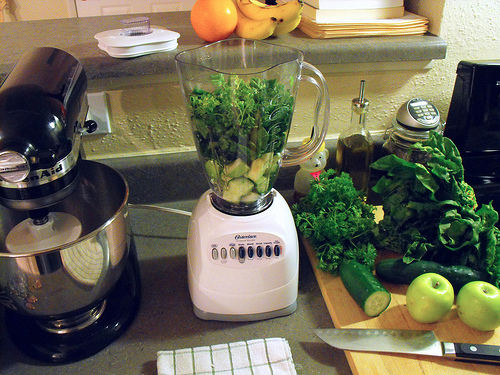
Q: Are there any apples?
A: Yes, there are apples.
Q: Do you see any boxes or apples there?
A: Yes, there are apples.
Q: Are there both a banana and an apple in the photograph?
A: Yes, there are both an apple and a banana.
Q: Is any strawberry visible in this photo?
A: No, there are no strawberries.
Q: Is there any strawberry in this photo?
A: No, there are no strawberries.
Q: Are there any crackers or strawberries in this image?
A: No, there are no strawberries or crackers.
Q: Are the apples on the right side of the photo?
A: Yes, the apples are on the right of the image.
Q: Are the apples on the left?
A: No, the apples are on the right of the image.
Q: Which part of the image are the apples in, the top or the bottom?
A: The apples are in the bottom of the image.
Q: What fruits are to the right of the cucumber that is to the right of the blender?
A: The fruits are apples.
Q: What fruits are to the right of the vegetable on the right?
A: The fruits are apples.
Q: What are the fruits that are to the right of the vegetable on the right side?
A: The fruits are apples.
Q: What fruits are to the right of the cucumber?
A: The fruits are apples.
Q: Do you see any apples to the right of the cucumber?
A: Yes, there are apples to the right of the cucumber.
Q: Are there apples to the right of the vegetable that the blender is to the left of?
A: Yes, there are apples to the right of the cucumber.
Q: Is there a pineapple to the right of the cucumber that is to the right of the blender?
A: No, there are apples to the right of the cucumber.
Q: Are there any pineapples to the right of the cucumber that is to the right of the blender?
A: No, there are apples to the right of the cucumber.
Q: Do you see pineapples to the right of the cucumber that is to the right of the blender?
A: No, there are apples to the right of the cucumber.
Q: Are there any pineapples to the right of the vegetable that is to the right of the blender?
A: No, there are apples to the right of the cucumber.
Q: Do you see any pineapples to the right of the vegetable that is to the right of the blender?
A: No, there are apples to the right of the cucumber.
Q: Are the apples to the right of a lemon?
A: No, the apples are to the right of the cucumber.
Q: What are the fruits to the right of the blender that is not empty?
A: The fruits are apples.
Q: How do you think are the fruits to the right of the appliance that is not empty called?
A: The fruits are apples.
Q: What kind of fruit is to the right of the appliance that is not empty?
A: The fruits are apples.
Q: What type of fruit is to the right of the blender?
A: The fruits are apples.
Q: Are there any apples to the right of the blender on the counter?
A: Yes, there are apples to the right of the blender.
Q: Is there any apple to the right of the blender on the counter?
A: Yes, there are apples to the right of the blender.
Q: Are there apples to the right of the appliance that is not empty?
A: Yes, there are apples to the right of the blender.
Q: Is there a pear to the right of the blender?
A: No, there are apples to the right of the blender.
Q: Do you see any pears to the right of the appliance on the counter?
A: No, there are apples to the right of the blender.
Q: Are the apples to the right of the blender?
A: Yes, the apples are to the right of the blender.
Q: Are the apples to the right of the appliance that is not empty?
A: Yes, the apples are to the right of the blender.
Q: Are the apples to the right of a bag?
A: No, the apples are to the right of the blender.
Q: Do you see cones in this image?
A: No, there are no cones.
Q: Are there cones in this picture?
A: No, there are no cones.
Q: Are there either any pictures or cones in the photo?
A: No, there are no cones or pictures.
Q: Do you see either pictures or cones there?
A: No, there are no cones or pictures.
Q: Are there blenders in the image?
A: Yes, there is a blender.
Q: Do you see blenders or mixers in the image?
A: Yes, there is a blender.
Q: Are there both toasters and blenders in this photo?
A: No, there is a blender but no toasters.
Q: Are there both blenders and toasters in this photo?
A: No, there is a blender but no toasters.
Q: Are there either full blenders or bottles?
A: Yes, there is a full blender.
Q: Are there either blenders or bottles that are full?
A: Yes, the blender is full.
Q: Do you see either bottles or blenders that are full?
A: Yes, the blender is full.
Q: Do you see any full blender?
A: Yes, there is a full blender.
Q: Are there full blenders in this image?
A: Yes, there is a full blender.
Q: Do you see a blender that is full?
A: Yes, there is a blender that is full.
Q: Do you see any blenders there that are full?
A: Yes, there is a blender that is full.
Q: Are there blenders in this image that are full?
A: Yes, there is a blender that is full.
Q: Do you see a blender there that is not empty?
A: Yes, there is an full blender.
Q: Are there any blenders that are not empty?
A: Yes, there is an full blender.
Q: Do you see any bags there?
A: No, there are no bags.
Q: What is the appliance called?
A: The appliance is a blender.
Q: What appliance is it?
A: The appliance is a blender.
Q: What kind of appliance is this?
A: That is a blender.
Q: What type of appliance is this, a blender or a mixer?
A: That is a blender.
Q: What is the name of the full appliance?
A: The appliance is a blender.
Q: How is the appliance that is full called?
A: The appliance is a blender.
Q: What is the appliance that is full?
A: The appliance is a blender.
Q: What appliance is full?
A: The appliance is a blender.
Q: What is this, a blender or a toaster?
A: This is a blender.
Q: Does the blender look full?
A: Yes, the blender is full.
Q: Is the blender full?
A: Yes, the blender is full.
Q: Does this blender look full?
A: Yes, the blender is full.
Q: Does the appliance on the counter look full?
A: Yes, the blender is full.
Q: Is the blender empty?
A: No, the blender is full.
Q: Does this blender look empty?
A: No, the blender is full.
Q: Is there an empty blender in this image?
A: No, there is a blender but it is full.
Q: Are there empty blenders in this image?
A: No, there is a blender but it is full.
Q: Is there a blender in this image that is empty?
A: No, there is a blender but it is full.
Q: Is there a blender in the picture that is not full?
A: No, there is a blender but it is full.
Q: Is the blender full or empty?
A: The blender is full.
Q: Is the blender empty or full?
A: The blender is full.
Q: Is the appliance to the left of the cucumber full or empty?
A: The blender is full.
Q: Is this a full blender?
A: Yes, this is a full blender.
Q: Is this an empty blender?
A: No, this is a full blender.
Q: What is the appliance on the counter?
A: The appliance is a blender.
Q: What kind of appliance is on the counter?
A: The appliance is a blender.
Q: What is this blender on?
A: The blender is on the counter.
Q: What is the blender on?
A: The blender is on the counter.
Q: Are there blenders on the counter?
A: Yes, there is a blender on the counter.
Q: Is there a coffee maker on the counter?
A: No, there is a blender on the counter.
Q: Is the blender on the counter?
A: Yes, the blender is on the counter.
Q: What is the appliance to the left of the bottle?
A: The appliance is a blender.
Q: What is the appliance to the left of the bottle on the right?
A: The appliance is a blender.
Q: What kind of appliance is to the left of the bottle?
A: The appliance is a blender.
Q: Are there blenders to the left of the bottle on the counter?
A: Yes, there is a blender to the left of the bottle.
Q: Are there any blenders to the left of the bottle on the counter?
A: Yes, there is a blender to the left of the bottle.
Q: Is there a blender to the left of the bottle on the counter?
A: Yes, there is a blender to the left of the bottle.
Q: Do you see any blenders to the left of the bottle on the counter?
A: Yes, there is a blender to the left of the bottle.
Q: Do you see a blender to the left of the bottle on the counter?
A: Yes, there is a blender to the left of the bottle.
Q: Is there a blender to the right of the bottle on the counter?
A: No, the blender is to the left of the bottle.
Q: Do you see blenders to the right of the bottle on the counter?
A: No, the blender is to the left of the bottle.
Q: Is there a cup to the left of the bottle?
A: No, there is a blender to the left of the bottle.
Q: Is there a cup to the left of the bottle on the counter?
A: No, there is a blender to the left of the bottle.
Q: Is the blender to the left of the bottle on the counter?
A: Yes, the blender is to the left of the bottle.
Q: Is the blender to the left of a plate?
A: No, the blender is to the left of the bottle.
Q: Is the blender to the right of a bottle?
A: No, the blender is to the left of a bottle.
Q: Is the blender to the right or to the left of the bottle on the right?
A: The blender is to the left of the bottle.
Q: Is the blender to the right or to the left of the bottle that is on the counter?
A: The blender is to the left of the bottle.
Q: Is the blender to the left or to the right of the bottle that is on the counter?
A: The blender is to the left of the bottle.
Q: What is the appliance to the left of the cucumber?
A: The appliance is a blender.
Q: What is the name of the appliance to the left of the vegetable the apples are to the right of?
A: The appliance is a blender.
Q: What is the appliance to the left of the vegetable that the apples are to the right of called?
A: The appliance is a blender.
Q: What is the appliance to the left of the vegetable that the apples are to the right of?
A: The appliance is a blender.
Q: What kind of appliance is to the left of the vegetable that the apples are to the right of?
A: The appliance is a blender.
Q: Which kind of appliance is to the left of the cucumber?
A: The appliance is a blender.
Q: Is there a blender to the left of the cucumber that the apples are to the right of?
A: Yes, there is a blender to the left of the cucumber.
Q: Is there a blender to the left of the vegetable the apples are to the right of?
A: Yes, there is a blender to the left of the cucumber.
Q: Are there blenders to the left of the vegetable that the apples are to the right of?
A: Yes, there is a blender to the left of the cucumber.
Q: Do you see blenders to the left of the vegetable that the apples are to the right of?
A: Yes, there is a blender to the left of the cucumber.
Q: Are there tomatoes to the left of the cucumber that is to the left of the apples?
A: No, there is a blender to the left of the cucumber.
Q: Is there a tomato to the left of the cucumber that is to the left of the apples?
A: No, there is a blender to the left of the cucumber.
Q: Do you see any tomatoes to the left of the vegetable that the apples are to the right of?
A: No, there is a blender to the left of the cucumber.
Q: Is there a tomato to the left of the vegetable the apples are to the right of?
A: No, there is a blender to the left of the cucumber.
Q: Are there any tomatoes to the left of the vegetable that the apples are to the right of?
A: No, there is a blender to the left of the cucumber.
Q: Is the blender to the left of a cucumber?
A: Yes, the blender is to the left of a cucumber.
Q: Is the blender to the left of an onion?
A: No, the blender is to the left of a cucumber.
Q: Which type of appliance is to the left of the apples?
A: The appliance is a blender.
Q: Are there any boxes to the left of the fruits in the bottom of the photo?
A: No, there is a blender to the left of the apples.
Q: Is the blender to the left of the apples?
A: Yes, the blender is to the left of the apples.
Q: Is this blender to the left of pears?
A: No, the blender is to the left of the apples.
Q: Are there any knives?
A: Yes, there is a knife.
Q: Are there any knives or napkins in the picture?
A: Yes, there is a knife.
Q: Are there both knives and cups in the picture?
A: No, there is a knife but no cups.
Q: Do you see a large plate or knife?
A: Yes, there is a large knife.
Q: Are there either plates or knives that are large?
A: Yes, the knife is large.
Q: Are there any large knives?
A: Yes, there is a large knife.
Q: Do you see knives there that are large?
A: Yes, there is a knife that is large.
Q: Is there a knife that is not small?
A: Yes, there is a large knife.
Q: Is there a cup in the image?
A: No, there are no cups.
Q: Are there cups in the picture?
A: No, there are no cups.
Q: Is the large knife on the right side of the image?
A: Yes, the knife is on the right of the image.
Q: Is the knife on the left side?
A: No, the knife is on the right of the image.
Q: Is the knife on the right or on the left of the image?
A: The knife is on the right of the image.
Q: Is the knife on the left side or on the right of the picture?
A: The knife is on the right of the image.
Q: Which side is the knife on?
A: The knife is on the right of the image.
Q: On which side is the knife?
A: The knife is on the right of the image.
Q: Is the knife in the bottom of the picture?
A: Yes, the knife is in the bottom of the image.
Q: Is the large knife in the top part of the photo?
A: No, the knife is in the bottom of the image.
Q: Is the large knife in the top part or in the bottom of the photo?
A: The knife is in the bottom of the image.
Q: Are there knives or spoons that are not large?
A: No, there is a knife but it is large.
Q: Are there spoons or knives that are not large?
A: No, there is a knife but it is large.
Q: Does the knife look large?
A: Yes, the knife is large.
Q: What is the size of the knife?
A: The knife is large.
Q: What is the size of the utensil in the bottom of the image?
A: The knife is large.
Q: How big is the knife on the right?
A: The knife is large.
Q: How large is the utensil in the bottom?
A: The knife is large.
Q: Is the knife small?
A: No, the knife is large.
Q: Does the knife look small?
A: No, the knife is large.